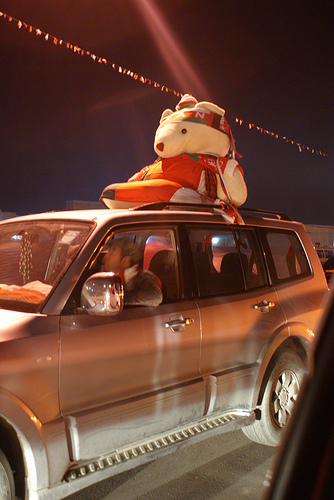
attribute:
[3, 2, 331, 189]
sky — night sky, Dark blue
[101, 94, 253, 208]
decoration — Inflatable, white polar bear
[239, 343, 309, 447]
tire — car tire, Black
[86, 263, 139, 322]
mirror — rear view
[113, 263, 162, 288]
scarf — winter scarf, Red and white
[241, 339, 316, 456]
left tire — Rear left tire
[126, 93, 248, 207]
teddy bear — large, white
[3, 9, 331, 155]
banner — flag banner, red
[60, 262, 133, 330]
mirror — Rear-view mirror, accessory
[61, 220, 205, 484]
door — driver's door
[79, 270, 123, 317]
mirror — side mirror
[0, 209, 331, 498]
suv — Silver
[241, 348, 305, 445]
tire — rear, vehicle, salted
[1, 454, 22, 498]
tire — salted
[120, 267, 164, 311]
coat — gray